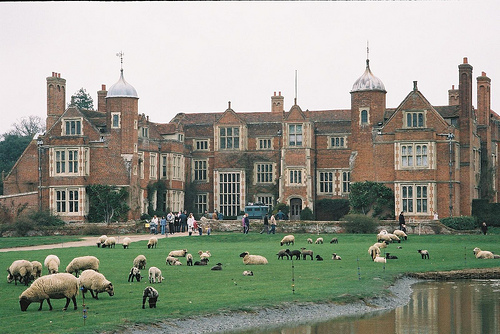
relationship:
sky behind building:
[191, 15, 217, 25] [132, 120, 279, 187]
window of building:
[219, 120, 234, 151] [132, 120, 279, 187]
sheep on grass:
[50, 272, 99, 292] [218, 282, 266, 297]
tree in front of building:
[341, 183, 386, 218] [132, 120, 279, 187]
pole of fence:
[12, 205, 24, 222] [0, 213, 116, 228]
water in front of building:
[432, 292, 465, 307] [132, 120, 279, 187]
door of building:
[288, 183, 303, 222] [132, 120, 279, 187]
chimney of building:
[273, 96, 282, 115] [132, 120, 279, 187]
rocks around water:
[254, 292, 302, 314] [432, 292, 465, 307]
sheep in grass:
[50, 272, 99, 292] [218, 282, 266, 297]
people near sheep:
[150, 224, 248, 239] [50, 272, 99, 292]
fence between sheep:
[0, 213, 116, 228] [50, 272, 99, 292]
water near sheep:
[432, 292, 465, 307] [50, 272, 99, 292]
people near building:
[150, 224, 248, 239] [132, 120, 279, 187]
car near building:
[246, 203, 275, 220] [132, 120, 279, 187]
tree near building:
[341, 183, 386, 218] [132, 120, 279, 187]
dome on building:
[98, 77, 136, 94] [132, 120, 279, 187]